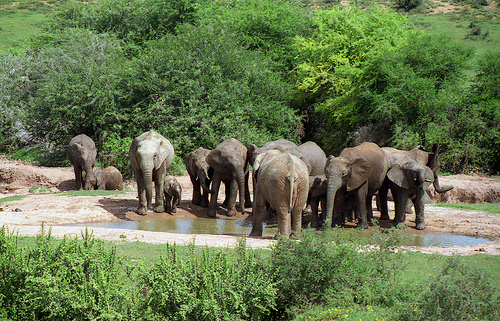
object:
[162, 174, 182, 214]
baby elephant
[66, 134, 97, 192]
elephant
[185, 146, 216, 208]
elephant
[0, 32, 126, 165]
trees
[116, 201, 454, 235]
muddy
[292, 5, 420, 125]
tree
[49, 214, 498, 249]
pool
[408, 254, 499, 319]
bushes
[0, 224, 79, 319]
bush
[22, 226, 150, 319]
bush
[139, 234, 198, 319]
bush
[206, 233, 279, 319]
bush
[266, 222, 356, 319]
bush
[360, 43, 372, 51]
leaves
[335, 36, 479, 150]
tree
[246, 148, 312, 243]
elephant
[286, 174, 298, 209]
tail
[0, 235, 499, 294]
grass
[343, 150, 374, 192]
ear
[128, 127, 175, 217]
elephant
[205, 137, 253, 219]
elephant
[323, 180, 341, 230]
trunk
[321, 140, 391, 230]
elephant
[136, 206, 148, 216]
elephant feet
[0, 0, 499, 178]
grass background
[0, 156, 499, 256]
dirt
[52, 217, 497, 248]
water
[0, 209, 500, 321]
forefront